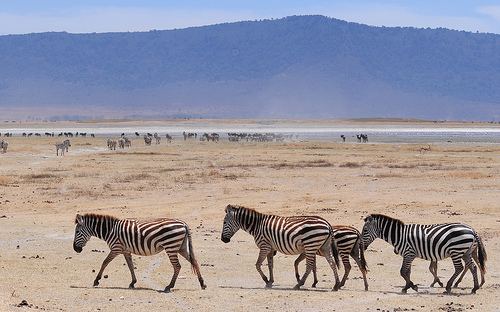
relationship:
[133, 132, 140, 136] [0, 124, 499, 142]
animal at edge of water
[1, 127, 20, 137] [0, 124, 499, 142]
animal at edge of water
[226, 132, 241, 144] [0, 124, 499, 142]
animal at edge of water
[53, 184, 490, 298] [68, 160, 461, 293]
zebras walking in a field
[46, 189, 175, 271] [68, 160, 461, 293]
zebra walking in a field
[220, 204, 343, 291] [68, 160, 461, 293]
zebras walking in a field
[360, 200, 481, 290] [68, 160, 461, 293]
zebra walking in a field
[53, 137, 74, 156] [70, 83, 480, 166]
zebra near water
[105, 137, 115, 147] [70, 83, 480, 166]
zebra near water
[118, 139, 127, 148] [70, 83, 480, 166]
zebra near water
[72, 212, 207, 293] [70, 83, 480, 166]
zebra near water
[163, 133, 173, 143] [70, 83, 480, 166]
zebra near water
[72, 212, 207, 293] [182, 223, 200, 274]
zebra has tail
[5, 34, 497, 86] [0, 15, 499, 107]
trees on mountain